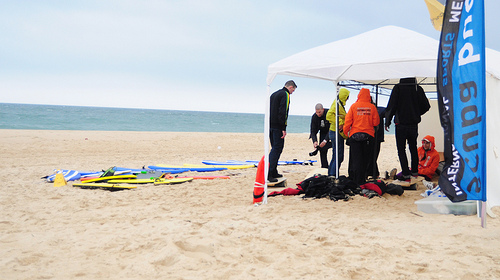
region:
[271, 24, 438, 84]
white tent canopy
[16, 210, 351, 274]
sandy beach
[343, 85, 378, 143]
person under the tent wearing an orange hooded jacket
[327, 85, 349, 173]
woman wearing jeans and a yellow hooded jacket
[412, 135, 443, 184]
person sitting down on the sand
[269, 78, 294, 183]
man wearing a black jacket with a stripe on the arm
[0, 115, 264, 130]
ocean water in the background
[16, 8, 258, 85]
clear skies above the ocean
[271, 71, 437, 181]
group of people on the beach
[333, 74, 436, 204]
people under the canopy of a white tent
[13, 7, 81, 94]
white clouds in blue sky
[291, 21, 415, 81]
white tent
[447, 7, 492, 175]
blue and white flag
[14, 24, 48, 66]
white clouds in blue sky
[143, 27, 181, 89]
white clouds in blue sky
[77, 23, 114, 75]
white clouds in blue sky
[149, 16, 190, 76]
white clouds in blue sky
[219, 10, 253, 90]
white clouds in blue sky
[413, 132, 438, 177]
a man sitting on the ground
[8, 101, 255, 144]
the ocean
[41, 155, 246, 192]
several surf boards on the ground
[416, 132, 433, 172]
a man wearing a orange jacket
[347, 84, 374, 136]
a person wearing a orange jacket with a hood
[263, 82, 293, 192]
a man standing on surf board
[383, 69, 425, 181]
a person wearing black clothing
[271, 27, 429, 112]
a white canopy tent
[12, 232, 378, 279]
tracks in the sand on a beach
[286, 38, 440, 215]
several people standing under a canopy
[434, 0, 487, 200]
a blue and black banner with text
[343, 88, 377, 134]
a bright orange jacket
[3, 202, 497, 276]
a sandy beach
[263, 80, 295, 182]
a man in a black wetsuit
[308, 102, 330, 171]
a man putting on socks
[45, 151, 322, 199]
a row of towels and beach gear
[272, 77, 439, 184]
a group of people at the beach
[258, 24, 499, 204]
a group of people under a white tent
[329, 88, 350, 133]
a yellow jacket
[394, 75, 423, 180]
a man dressed in black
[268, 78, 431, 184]
people standing on a beach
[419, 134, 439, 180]
man sitting on the sand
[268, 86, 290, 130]
man wearing a black shirt with yellow lines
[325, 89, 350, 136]
person wearing a yellow windbreaker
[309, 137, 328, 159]
a man putting on black socks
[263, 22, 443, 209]
a white canopy on the beach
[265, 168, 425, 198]
equipment underneath a canopy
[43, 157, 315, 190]
equipment on the sand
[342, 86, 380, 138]
person wearing an orange windbreaker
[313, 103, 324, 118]
man with gray hair